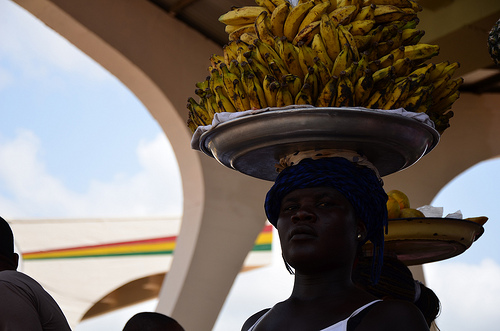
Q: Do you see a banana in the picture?
A: Yes, there is a banana.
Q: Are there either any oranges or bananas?
A: Yes, there is a banana.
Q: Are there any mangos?
A: No, there are no mangos.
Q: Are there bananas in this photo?
A: Yes, there is a banana.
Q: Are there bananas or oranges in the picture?
A: Yes, there is a banana.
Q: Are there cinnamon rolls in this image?
A: No, there are no cinnamon rolls.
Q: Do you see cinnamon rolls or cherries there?
A: No, there are no cinnamon rolls or cherries.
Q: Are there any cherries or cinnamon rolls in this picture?
A: No, there are no cinnamon rolls or cherries.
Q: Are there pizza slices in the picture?
A: No, there are no pizza slices.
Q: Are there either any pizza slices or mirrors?
A: No, there are no pizza slices or mirrors.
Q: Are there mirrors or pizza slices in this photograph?
A: No, there are no pizza slices or mirrors.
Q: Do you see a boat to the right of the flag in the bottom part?
A: No, there is a tray to the right of the flag.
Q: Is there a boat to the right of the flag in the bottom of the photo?
A: No, there is a tray to the right of the flag.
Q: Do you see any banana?
A: Yes, there are bananas.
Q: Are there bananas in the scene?
A: Yes, there are bananas.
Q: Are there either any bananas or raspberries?
A: Yes, there are bananas.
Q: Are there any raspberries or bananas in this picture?
A: Yes, there are bananas.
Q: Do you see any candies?
A: No, there are no candies.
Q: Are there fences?
A: No, there are no fences.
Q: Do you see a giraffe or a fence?
A: No, there are no fences or giraffes.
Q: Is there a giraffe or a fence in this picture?
A: No, there are no fences or giraffes.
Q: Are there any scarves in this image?
A: Yes, there is a scarf.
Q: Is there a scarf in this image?
A: Yes, there is a scarf.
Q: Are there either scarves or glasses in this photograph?
A: Yes, there is a scarf.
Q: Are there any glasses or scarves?
A: Yes, there is a scarf.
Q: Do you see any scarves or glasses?
A: Yes, there is a scarf.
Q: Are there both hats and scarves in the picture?
A: No, there is a scarf but no hats.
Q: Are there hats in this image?
A: No, there are no hats.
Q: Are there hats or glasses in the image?
A: No, there are no hats or glasses.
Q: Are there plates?
A: Yes, there is a plate.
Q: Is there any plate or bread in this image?
A: Yes, there is a plate.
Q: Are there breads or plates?
A: Yes, there is a plate.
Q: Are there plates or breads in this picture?
A: Yes, there is a plate.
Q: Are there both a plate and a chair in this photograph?
A: No, there is a plate but no chairs.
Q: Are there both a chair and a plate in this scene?
A: No, there is a plate but no chairs.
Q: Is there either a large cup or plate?
A: Yes, there is a large plate.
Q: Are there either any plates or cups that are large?
A: Yes, the plate is large.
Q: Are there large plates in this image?
A: Yes, there is a large plate.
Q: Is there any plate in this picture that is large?
A: Yes, there is a plate that is large.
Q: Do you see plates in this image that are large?
A: Yes, there is a plate that is large.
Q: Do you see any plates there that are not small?
A: Yes, there is a large plate.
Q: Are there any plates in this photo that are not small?
A: Yes, there is a large plate.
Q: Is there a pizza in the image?
A: No, there are no pizzas.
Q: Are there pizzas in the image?
A: No, there are no pizzas.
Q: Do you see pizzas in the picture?
A: No, there are no pizzas.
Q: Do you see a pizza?
A: No, there are no pizzas.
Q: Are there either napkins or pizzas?
A: No, there are no pizzas or napkins.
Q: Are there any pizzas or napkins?
A: No, there are no pizzas or napkins.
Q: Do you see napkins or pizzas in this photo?
A: No, there are no pizzas or napkins.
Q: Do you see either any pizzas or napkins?
A: No, there are no pizzas or napkins.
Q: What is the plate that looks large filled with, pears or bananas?
A: The plate is filled with bananas.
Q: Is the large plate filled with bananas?
A: Yes, the plate is filled with bananas.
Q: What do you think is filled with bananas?
A: The plate is filled with bananas.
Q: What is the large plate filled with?
A: The plate is filled with bananas.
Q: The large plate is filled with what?
A: The plate is filled with bananas.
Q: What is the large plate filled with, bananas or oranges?
A: The plate is filled with bananas.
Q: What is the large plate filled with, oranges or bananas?
A: The plate is filled with bananas.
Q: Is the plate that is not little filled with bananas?
A: Yes, the plate is filled with bananas.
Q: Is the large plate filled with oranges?
A: No, the plate is filled with bananas.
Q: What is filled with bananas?
A: The plate is filled with bananas.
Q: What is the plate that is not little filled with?
A: The plate is filled with bananas.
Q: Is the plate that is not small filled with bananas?
A: Yes, the plate is filled with bananas.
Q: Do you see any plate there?
A: Yes, there is a plate.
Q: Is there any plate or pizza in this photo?
A: Yes, there is a plate.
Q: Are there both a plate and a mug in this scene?
A: No, there is a plate but no mugs.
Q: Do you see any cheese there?
A: No, there is no cheese.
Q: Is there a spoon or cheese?
A: No, there are no cheese or spoons.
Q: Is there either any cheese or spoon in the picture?
A: No, there are no cheese or spoons.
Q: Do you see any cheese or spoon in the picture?
A: No, there are no cheese or spoons.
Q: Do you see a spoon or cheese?
A: No, there are no cheese or spoons.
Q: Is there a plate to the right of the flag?
A: Yes, there is a plate to the right of the flag.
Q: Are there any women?
A: Yes, there is a woman.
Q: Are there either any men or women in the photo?
A: Yes, there is a woman.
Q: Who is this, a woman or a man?
A: This is a woman.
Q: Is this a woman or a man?
A: This is a woman.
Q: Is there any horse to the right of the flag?
A: No, there is a woman to the right of the flag.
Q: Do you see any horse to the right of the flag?
A: No, there is a woman to the right of the flag.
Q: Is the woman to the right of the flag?
A: Yes, the woman is to the right of the flag.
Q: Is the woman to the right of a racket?
A: No, the woman is to the right of the flag.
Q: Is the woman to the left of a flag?
A: No, the woman is to the right of a flag.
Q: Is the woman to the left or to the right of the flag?
A: The woman is to the right of the flag.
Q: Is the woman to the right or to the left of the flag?
A: The woman is to the right of the flag.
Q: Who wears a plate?
A: The woman wears a plate.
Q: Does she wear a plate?
A: Yes, the woman wears a plate.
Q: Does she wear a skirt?
A: No, the woman wears a plate.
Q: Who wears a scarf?
A: The woman wears a scarf.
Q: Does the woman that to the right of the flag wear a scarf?
A: Yes, the woman wears a scarf.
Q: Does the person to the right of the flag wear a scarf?
A: Yes, the woman wears a scarf.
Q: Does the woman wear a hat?
A: No, the woman wears a scarf.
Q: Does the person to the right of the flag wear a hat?
A: No, the woman wears a scarf.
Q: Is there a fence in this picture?
A: No, there are no fences.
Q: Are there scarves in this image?
A: Yes, there is a scarf.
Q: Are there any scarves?
A: Yes, there is a scarf.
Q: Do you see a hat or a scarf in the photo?
A: Yes, there is a scarf.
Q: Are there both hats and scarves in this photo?
A: No, there is a scarf but no hats.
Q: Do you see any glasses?
A: No, there are no glasses.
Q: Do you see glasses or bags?
A: No, there are no glasses or bags.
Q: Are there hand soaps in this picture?
A: No, there are no hand soaps.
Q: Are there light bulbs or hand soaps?
A: No, there are no hand soaps or light bulbs.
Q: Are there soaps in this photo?
A: No, there are no soaps.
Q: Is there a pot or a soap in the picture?
A: No, there are no soaps or pots.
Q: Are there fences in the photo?
A: No, there are no fences.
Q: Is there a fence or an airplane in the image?
A: No, there are no fences or airplanes.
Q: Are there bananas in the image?
A: Yes, there is a banana.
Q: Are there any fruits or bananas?
A: Yes, there is a banana.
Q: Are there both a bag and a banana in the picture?
A: No, there is a banana but no bags.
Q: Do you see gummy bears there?
A: No, there are no gummy bears.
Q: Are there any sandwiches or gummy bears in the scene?
A: No, there are no gummy bears or sandwiches.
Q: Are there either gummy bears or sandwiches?
A: No, there are no gummy bears or sandwiches.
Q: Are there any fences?
A: No, there are no fences.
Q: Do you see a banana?
A: Yes, there is a banana.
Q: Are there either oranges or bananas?
A: Yes, there is a banana.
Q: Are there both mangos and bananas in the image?
A: No, there is a banana but no mangoes.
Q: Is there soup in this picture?
A: No, there is no soup.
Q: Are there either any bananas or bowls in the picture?
A: Yes, there is a banana.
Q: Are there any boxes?
A: No, there are no boxes.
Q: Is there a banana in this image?
A: Yes, there are bananas.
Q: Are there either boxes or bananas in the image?
A: Yes, there are bananas.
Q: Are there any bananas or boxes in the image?
A: Yes, there are bananas.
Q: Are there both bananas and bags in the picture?
A: No, there are bananas but no bags.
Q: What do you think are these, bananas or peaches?
A: These are bananas.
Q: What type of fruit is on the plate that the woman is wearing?
A: The fruits are bananas.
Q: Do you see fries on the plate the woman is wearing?
A: No, there are bananas on the plate.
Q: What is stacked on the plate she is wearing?
A: The bananas are stacked on the plate.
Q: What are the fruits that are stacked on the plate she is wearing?
A: The fruits are bananas.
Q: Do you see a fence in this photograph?
A: No, there are no fences.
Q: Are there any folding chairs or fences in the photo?
A: No, there are no fences or folding chairs.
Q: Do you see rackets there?
A: No, there are no rackets.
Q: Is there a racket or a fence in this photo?
A: No, there are no rackets or fences.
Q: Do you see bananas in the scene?
A: Yes, there are bananas.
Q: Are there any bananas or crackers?
A: Yes, there are bananas.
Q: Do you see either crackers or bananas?
A: Yes, there are bananas.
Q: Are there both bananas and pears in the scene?
A: No, there are bananas but no pears.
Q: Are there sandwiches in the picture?
A: No, there are no sandwiches.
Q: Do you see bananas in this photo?
A: Yes, there are bananas.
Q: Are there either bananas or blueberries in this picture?
A: Yes, there are bananas.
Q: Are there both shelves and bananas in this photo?
A: No, there are bananas but no shelves.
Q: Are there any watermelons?
A: No, there are no watermelons.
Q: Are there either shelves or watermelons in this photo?
A: No, there are no watermelons or shelves.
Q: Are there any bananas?
A: Yes, there are bananas.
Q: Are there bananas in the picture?
A: Yes, there are bananas.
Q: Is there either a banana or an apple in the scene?
A: Yes, there are bananas.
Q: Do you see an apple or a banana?
A: Yes, there are bananas.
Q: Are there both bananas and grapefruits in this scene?
A: No, there are bananas but no grapefruits.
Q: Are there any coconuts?
A: No, there are no coconuts.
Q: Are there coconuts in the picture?
A: No, there are no coconuts.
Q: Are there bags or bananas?
A: Yes, there are bananas.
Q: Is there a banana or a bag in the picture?
A: Yes, there are bananas.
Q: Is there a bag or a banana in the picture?
A: Yes, there are bananas.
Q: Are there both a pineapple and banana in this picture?
A: No, there are bananas but no pineapples.